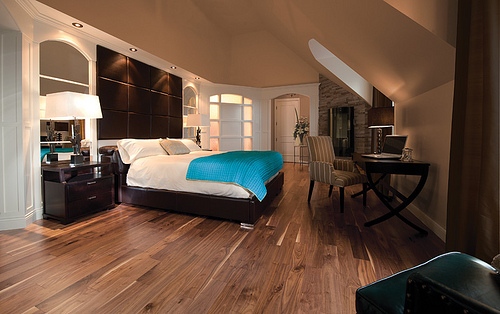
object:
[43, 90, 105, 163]
lamp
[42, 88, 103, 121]
shade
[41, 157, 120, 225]
nightstand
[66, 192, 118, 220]
drawers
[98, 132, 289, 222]
bed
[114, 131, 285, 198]
linens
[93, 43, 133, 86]
rectangle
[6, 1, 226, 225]
wall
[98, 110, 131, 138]
rectangle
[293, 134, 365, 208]
chair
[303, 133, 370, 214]
upholstery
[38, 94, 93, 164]
mirror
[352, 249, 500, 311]
chair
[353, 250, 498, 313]
leather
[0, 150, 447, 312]
floor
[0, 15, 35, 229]
planks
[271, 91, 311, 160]
door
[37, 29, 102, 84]
lighting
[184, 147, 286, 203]
bedspread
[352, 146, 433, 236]
table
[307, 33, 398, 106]
skylight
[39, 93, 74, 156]
reflection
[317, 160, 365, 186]
cushion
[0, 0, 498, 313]
bedroom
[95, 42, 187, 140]
decoration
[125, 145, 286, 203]
sheet